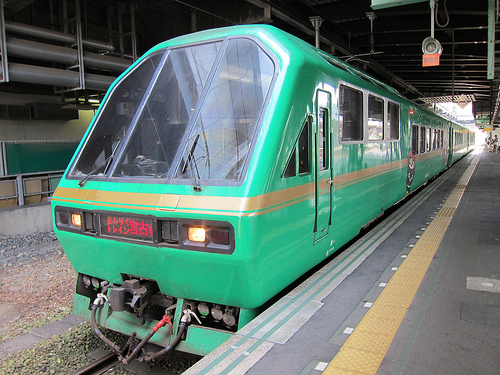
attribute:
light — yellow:
[68, 209, 80, 228]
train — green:
[49, 18, 476, 353]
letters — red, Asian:
[108, 215, 154, 239]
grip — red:
[152, 311, 175, 330]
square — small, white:
[315, 359, 329, 372]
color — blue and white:
[254, 315, 289, 346]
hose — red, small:
[150, 315, 179, 335]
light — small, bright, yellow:
[183, 227, 209, 243]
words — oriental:
[106, 218, 156, 240]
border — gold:
[49, 157, 399, 219]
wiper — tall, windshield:
[175, 135, 215, 190]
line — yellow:
[325, 295, 413, 373]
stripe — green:
[285, 304, 303, 337]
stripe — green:
[260, 293, 293, 315]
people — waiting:
[480, 131, 497, 158]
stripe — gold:
[60, 138, 477, 221]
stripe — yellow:
[315, 149, 481, 372]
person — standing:
[484, 132, 498, 157]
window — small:
[333, 76, 367, 147]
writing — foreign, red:
[95, 208, 154, 241]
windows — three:
[76, 35, 282, 195]